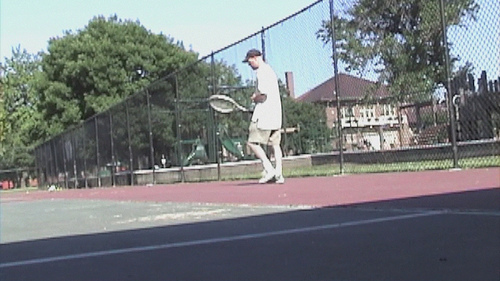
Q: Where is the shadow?
A: On the ground.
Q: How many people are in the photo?
A: 1.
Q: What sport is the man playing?
A: Tennis.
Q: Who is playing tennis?
A: The man.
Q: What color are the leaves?
A: Green.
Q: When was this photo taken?
A: During the day.